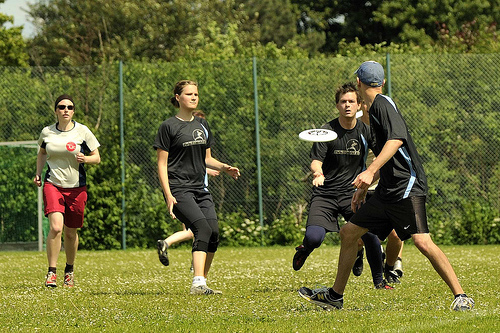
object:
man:
[352, 88, 403, 285]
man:
[157, 110, 207, 266]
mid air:
[280, 14, 346, 61]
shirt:
[38, 119, 101, 189]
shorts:
[349, 193, 433, 242]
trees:
[24, 1, 104, 66]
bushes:
[0, 0, 499, 248]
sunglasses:
[56, 105, 74, 109]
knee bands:
[182, 199, 220, 240]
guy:
[299, 60, 476, 311]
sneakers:
[451, 294, 473, 313]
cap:
[352, 60, 384, 87]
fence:
[1, 61, 499, 248]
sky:
[6, 4, 44, 34]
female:
[34, 94, 101, 287]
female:
[152, 79, 241, 296]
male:
[291, 80, 395, 290]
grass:
[4, 249, 494, 332]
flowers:
[2, 246, 499, 333]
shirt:
[153, 116, 212, 188]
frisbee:
[298, 128, 338, 142]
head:
[352, 59, 388, 92]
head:
[335, 82, 361, 118]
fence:
[12, 65, 484, 232]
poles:
[113, 57, 284, 239]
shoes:
[298, 285, 344, 311]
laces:
[311, 287, 330, 298]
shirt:
[365, 92, 428, 202]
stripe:
[395, 147, 414, 171]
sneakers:
[45, 268, 59, 287]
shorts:
[41, 181, 89, 229]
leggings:
[168, 186, 229, 253]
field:
[0, 238, 499, 333]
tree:
[168, 17, 246, 194]